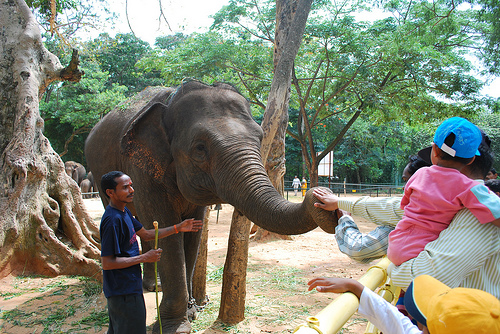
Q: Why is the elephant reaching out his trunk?
A: To reach the people.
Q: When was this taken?
A: During the day.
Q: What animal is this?
A: Elephant.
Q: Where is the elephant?
A: Near the man.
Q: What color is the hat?
A: Blue.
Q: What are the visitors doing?
A: Looking at the elephant.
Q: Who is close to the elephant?
A: The man in navy.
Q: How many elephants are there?
A: One.